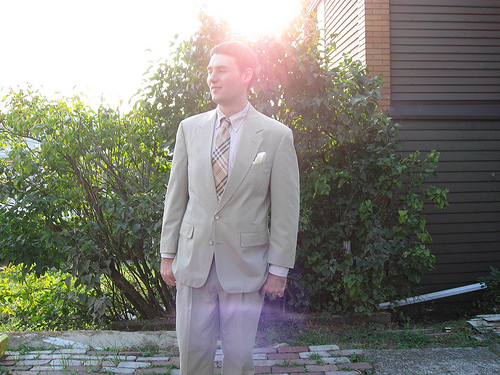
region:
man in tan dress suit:
[163, 30, 315, 373]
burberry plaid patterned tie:
[211, 115, 236, 200]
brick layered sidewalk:
[298, 341, 377, 373]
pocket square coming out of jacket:
[248, 149, 266, 170]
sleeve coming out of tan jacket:
[264, 263, 288, 283]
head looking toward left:
[194, 32, 261, 122]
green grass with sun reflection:
[1, 255, 93, 325]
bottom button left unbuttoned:
[204, 260, 225, 275]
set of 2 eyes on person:
[196, 64, 231, 76]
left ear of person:
[241, 64, 259, 91]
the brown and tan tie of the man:
[211, 115, 233, 197]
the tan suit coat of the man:
[160, 111, 297, 285]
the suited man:
[153, 40, 296, 374]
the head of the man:
[203, 42, 257, 109]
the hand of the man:
[265, 273, 286, 296]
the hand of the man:
[159, 257, 179, 284]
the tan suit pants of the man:
[172, 280, 259, 371]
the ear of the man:
[245, 67, 256, 82]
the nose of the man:
[207, 71, 216, 81]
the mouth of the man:
[209, 83, 221, 92]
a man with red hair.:
[192, 37, 282, 112]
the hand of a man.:
[250, 265, 312, 311]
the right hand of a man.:
[153, 238, 177, 290]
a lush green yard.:
[3, 234, 157, 347]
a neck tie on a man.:
[202, 115, 244, 207]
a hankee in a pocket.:
[243, 141, 278, 186]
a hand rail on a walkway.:
[363, 265, 488, 330]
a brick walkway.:
[0, 328, 417, 369]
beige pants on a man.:
[165, 265, 282, 372]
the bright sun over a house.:
[198, 0, 308, 49]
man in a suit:
[141, 41, 333, 373]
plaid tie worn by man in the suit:
[208, 116, 242, 199]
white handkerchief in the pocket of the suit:
[250, 153, 278, 171]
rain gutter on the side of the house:
[375, 285, 498, 313]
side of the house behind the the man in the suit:
[322, 2, 447, 158]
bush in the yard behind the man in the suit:
[7, 103, 162, 315]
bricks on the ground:
[36, 336, 173, 373]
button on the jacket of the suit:
[208, 208, 226, 225]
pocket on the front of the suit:
[173, 223, 210, 250]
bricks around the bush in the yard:
[291, 300, 406, 336]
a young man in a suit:
[157, 40, 300, 372]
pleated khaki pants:
[174, 254, 264, 374]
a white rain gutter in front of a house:
[371, 281, 488, 312]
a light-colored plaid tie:
[212, 117, 228, 201]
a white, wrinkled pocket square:
[251, 151, 268, 164]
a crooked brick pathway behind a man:
[0, 344, 377, 374]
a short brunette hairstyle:
[210, 39, 256, 89]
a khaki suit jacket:
[158, 108, 298, 293]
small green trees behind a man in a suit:
[0, 15, 450, 324]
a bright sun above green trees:
[220, 3, 300, 43]